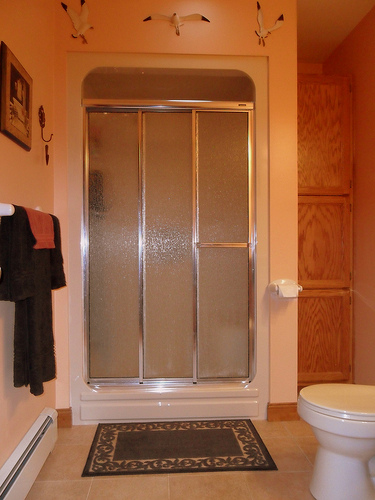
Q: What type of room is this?
A: It is a bathroom.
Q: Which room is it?
A: It is a bathroom.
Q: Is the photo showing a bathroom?
A: Yes, it is showing a bathroom.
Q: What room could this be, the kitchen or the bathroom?
A: It is the bathroom.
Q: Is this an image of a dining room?
A: No, the picture is showing a bathroom.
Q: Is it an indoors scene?
A: Yes, it is indoors.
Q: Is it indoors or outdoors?
A: It is indoors.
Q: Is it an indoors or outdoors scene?
A: It is indoors.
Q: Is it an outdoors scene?
A: No, it is indoors.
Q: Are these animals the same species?
A: Yes, all the animals are birds.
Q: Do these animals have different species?
A: No, all the animals are birds.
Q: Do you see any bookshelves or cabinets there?
A: Yes, there is a cabinet.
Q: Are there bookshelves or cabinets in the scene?
A: Yes, there is a cabinet.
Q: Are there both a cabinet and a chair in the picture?
A: No, there is a cabinet but no chairs.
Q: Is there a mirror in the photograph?
A: No, there are no mirrors.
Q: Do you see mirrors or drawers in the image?
A: No, there are no mirrors or drawers.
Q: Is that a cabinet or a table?
A: That is a cabinet.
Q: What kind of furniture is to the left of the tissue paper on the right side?
A: The piece of furniture is a cabinet.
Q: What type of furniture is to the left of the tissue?
A: The piece of furniture is a cabinet.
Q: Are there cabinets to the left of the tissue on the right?
A: Yes, there is a cabinet to the left of the tissue.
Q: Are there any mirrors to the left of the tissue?
A: No, there is a cabinet to the left of the tissue.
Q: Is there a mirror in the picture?
A: No, there are no mirrors.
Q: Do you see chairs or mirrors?
A: No, there are no mirrors or chairs.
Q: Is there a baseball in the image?
A: No, there are no baseballs.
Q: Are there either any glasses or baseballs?
A: No, there are no baseballs or glasses.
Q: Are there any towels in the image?
A: Yes, there is a towel.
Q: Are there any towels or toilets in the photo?
A: Yes, there is a towel.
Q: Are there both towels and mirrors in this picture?
A: No, there is a towel but no mirrors.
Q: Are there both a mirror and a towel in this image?
A: No, there is a towel but no mirrors.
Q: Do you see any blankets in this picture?
A: No, there are no blankets.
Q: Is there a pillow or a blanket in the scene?
A: No, there are no blankets or pillows.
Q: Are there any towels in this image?
A: Yes, there is a towel.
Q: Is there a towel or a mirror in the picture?
A: Yes, there is a towel.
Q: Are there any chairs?
A: No, there are no chairs.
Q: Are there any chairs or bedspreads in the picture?
A: No, there are no chairs or bedspreads.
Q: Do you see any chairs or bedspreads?
A: No, there are no chairs or bedspreads.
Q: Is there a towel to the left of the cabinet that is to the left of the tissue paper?
A: Yes, there is a towel to the left of the cabinet.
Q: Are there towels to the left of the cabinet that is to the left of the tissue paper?
A: Yes, there is a towel to the left of the cabinet.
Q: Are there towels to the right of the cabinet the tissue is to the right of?
A: No, the towel is to the left of the cabinet.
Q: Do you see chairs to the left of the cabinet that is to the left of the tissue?
A: No, there is a towel to the left of the cabinet.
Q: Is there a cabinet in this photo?
A: Yes, there is a cabinet.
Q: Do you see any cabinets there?
A: Yes, there is a cabinet.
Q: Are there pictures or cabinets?
A: Yes, there is a cabinet.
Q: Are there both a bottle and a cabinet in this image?
A: No, there is a cabinet but no bottles.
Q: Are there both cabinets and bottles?
A: No, there is a cabinet but no bottles.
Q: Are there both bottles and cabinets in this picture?
A: No, there is a cabinet but no bottles.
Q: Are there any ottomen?
A: No, there are no ottomen.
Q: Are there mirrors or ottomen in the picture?
A: No, there are no ottomen or mirrors.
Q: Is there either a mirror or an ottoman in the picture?
A: No, there are no ottomen or mirrors.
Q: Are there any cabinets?
A: Yes, there is a cabinet.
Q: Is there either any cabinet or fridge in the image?
A: Yes, there is a cabinet.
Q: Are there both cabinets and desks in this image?
A: No, there is a cabinet but no desks.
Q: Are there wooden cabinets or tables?
A: Yes, there is a wood cabinet.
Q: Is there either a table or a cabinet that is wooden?
A: Yes, the cabinet is wooden.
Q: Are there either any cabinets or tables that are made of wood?
A: Yes, the cabinet is made of wood.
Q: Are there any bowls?
A: No, there are no bowls.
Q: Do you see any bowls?
A: No, there are no bowls.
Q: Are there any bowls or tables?
A: No, there are no bowls or tables.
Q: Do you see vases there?
A: No, there are no vases.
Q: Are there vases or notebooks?
A: No, there are no vases or notebooks.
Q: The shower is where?
A: The shower is in the bathroom.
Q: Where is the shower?
A: The shower is in the bathroom.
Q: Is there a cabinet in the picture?
A: Yes, there is a cabinet.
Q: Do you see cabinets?
A: Yes, there is a cabinet.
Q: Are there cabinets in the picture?
A: Yes, there is a cabinet.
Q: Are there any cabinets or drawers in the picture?
A: Yes, there is a cabinet.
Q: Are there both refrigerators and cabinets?
A: No, there is a cabinet but no refrigerators.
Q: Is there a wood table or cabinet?
A: Yes, there is a wood cabinet.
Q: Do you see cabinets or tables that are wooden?
A: Yes, the cabinet is wooden.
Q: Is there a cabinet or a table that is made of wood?
A: Yes, the cabinet is made of wood.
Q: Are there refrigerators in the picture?
A: No, there are no refrigerators.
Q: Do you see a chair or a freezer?
A: No, there are no refrigerators or chairs.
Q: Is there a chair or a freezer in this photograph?
A: No, there are no refrigerators or chairs.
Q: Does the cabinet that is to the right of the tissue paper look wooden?
A: Yes, the cabinet is wooden.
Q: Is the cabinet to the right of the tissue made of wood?
A: Yes, the cabinet is made of wood.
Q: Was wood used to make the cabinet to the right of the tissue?
A: Yes, the cabinet is made of wood.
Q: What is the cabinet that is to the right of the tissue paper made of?
A: The cabinet is made of wood.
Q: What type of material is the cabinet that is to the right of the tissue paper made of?
A: The cabinet is made of wood.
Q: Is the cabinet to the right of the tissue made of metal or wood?
A: The cabinet is made of wood.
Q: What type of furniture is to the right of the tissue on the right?
A: The piece of furniture is a cabinet.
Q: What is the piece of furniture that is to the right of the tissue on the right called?
A: The piece of furniture is a cabinet.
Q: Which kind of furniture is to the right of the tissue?
A: The piece of furniture is a cabinet.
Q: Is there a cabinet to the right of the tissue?
A: Yes, there is a cabinet to the right of the tissue.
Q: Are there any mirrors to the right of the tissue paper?
A: No, there is a cabinet to the right of the tissue paper.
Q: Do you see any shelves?
A: No, there are no shelves.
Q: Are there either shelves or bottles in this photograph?
A: No, there are no shelves or bottles.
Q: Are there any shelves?
A: No, there are no shelves.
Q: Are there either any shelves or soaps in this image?
A: No, there are no shelves or soaps.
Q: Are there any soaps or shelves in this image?
A: No, there are no shelves or soaps.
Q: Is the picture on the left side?
A: Yes, the picture is on the left of the image.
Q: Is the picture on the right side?
A: No, the picture is on the left of the image.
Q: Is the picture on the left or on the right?
A: The picture is on the left of the image.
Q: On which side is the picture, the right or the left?
A: The picture is on the left of the image.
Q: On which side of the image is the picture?
A: The picture is on the left of the image.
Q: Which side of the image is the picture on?
A: The picture is on the left of the image.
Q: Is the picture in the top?
A: Yes, the picture is in the top of the image.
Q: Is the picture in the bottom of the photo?
A: No, the picture is in the top of the image.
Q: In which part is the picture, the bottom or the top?
A: The picture is in the top of the image.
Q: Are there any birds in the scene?
A: Yes, there is a bird.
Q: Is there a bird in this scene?
A: Yes, there is a bird.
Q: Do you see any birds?
A: Yes, there is a bird.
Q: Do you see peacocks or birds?
A: Yes, there is a bird.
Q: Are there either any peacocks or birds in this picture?
A: Yes, there is a bird.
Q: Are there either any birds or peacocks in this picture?
A: Yes, there is a bird.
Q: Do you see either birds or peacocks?
A: Yes, there is a bird.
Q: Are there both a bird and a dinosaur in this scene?
A: No, there is a bird but no dinosaurs.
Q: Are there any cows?
A: No, there are no cows.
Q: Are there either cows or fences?
A: No, there are no cows or fences.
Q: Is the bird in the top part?
A: Yes, the bird is in the top of the image.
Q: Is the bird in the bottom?
A: No, the bird is in the top of the image.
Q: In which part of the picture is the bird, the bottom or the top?
A: The bird is in the top of the image.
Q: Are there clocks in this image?
A: No, there are no clocks.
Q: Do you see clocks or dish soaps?
A: No, there are no clocks or dish soaps.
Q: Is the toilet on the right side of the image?
A: Yes, the toilet is on the right of the image.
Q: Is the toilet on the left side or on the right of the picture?
A: The toilet is on the right of the image.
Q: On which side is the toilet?
A: The toilet is on the right of the image.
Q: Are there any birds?
A: Yes, there is a bird.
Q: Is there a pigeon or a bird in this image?
A: Yes, there is a bird.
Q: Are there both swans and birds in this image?
A: No, there is a bird but no swans.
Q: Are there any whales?
A: No, there are no whales.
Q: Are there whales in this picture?
A: No, there are no whales.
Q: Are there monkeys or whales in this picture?
A: No, there are no whales or monkeys.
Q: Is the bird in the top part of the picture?
A: Yes, the bird is in the top of the image.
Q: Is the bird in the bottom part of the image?
A: No, the bird is in the top of the image.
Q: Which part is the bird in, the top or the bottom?
A: The bird is in the top of the image.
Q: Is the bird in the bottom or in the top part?
A: The bird is in the top of the image.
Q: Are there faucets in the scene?
A: No, there are no faucets.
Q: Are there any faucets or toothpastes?
A: No, there are no faucets or toothpastes.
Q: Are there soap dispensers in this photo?
A: No, there are no soap dispensers.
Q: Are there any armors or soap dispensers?
A: No, there are no soap dispensers or armors.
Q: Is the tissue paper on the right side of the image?
A: Yes, the tissue paper is on the right of the image.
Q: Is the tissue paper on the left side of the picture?
A: No, the tissue paper is on the right of the image.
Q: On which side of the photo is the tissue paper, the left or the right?
A: The tissue paper is on the right of the image.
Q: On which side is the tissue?
A: The tissue is on the right of the image.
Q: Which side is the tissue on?
A: The tissue is on the right of the image.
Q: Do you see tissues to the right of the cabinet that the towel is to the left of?
A: Yes, there is a tissue to the right of the cabinet.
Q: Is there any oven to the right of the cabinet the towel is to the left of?
A: No, there is a tissue to the right of the cabinet.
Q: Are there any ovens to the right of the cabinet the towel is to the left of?
A: No, there is a tissue to the right of the cabinet.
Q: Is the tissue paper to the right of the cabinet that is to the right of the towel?
A: Yes, the tissue paper is to the right of the cabinet.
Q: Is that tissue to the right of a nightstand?
A: No, the tissue is to the right of the cabinet.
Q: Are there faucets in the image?
A: No, there are no faucets.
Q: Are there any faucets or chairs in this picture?
A: No, there are no faucets or chairs.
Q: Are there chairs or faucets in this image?
A: No, there are no faucets or chairs.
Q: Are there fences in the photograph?
A: No, there are no fences.